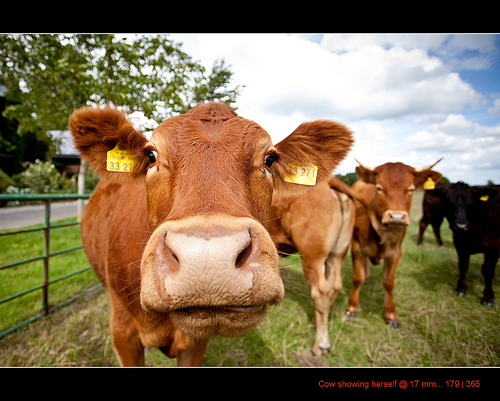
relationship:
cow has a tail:
[68, 100, 355, 365] [329, 173, 376, 219]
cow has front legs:
[349, 158, 444, 328] [352, 257, 406, 313]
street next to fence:
[5, 184, 53, 246] [19, 196, 89, 333]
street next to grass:
[5, 184, 53, 246] [47, 310, 92, 355]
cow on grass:
[68, 100, 355, 365] [1, 185, 499, 365]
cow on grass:
[274, 169, 381, 362] [1, 185, 499, 365]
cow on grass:
[342, 155, 444, 328] [1, 185, 499, 365]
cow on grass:
[413, 175, 472, 244] [1, 185, 499, 365]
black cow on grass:
[447, 180, 500, 307] [1, 185, 499, 365]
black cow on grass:
[447, 180, 500, 307] [0, 216, 107, 365]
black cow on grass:
[447, 180, 500, 307] [260, 235, 497, 368]